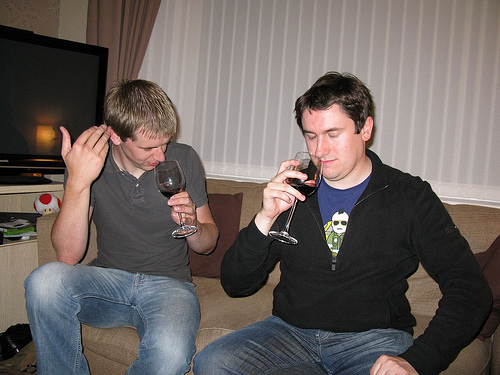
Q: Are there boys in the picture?
A: No, there are no boys.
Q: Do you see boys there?
A: No, there are no boys.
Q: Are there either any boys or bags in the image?
A: No, there are no boys or bags.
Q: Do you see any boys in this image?
A: No, there are no boys.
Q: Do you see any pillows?
A: Yes, there is a pillow.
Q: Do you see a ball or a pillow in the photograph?
A: Yes, there is a pillow.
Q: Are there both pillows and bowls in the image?
A: No, there is a pillow but no bowls.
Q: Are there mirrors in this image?
A: No, there are no mirrors.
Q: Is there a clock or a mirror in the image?
A: No, there are no mirrors or clocks.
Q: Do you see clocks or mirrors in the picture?
A: No, there are no mirrors or clocks.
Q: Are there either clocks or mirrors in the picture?
A: No, there are no mirrors or clocks.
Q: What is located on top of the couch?
A: The pillow is on top of the couch.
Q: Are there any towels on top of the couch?
A: No, there is a pillow on top of the couch.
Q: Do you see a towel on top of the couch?
A: No, there is a pillow on top of the couch.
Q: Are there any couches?
A: Yes, there is a couch.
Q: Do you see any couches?
A: Yes, there is a couch.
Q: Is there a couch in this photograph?
A: Yes, there is a couch.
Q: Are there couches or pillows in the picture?
A: Yes, there is a couch.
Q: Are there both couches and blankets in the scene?
A: No, there is a couch but no blankets.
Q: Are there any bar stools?
A: No, there are no bar stools.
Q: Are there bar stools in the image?
A: No, there are no bar stools.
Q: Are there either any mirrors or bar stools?
A: No, there are no bar stools or mirrors.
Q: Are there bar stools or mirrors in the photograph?
A: No, there are no bar stools or mirrors.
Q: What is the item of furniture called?
A: The piece of furniture is a couch.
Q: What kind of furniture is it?
A: The piece of furniture is a couch.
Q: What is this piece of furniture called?
A: This is a couch.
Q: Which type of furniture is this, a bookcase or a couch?
A: This is a couch.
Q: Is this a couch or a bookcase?
A: This is a couch.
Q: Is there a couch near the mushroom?
A: Yes, there is a couch near the mushroom.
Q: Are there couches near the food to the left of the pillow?
A: Yes, there is a couch near the mushroom.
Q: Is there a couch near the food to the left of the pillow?
A: Yes, there is a couch near the mushroom.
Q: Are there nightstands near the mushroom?
A: No, there is a couch near the mushroom.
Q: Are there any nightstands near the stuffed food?
A: No, there is a couch near the mushroom.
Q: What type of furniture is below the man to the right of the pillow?
A: The piece of furniture is a couch.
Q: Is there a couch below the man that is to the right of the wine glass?
A: Yes, there is a couch below the man.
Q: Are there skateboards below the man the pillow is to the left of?
A: No, there is a couch below the man.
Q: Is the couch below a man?
A: Yes, the couch is below a man.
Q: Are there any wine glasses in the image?
A: Yes, there is a wine glass.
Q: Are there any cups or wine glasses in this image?
A: Yes, there is a wine glass.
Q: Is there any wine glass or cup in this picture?
A: Yes, there is a wine glass.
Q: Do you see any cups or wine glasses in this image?
A: Yes, there is a wine glass.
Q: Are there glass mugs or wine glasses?
A: Yes, there is a glass wine glass.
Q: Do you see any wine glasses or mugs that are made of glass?
A: Yes, the wine glass is made of glass.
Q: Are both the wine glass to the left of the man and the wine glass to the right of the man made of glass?
A: Yes, both the wine glass and the wine glass are made of glass.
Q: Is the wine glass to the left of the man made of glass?
A: Yes, the wineglass is made of glass.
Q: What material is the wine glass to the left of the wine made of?
A: The wine glass is made of glass.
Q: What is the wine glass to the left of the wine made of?
A: The wine glass is made of glass.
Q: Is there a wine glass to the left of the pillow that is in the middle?
A: Yes, there is a wine glass to the left of the pillow.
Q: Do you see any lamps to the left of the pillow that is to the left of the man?
A: No, there is a wine glass to the left of the pillow.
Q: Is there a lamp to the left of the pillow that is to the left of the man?
A: No, there is a wine glass to the left of the pillow.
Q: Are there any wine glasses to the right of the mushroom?
A: Yes, there is a wine glass to the right of the mushroom.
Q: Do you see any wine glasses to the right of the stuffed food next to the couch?
A: Yes, there is a wine glass to the right of the mushroom.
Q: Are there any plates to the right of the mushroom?
A: No, there is a wine glass to the right of the mushroom.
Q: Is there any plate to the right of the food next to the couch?
A: No, there is a wine glass to the right of the mushroom.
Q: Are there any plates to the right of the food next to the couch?
A: No, there is a wine glass to the right of the mushroom.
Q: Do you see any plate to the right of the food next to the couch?
A: No, there is a wine glass to the right of the mushroom.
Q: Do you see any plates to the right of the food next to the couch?
A: No, there is a wine glass to the right of the mushroom.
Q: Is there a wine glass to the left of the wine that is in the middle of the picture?
A: Yes, there is a wine glass to the left of the wine.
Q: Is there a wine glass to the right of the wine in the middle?
A: No, the wine glass is to the left of the wine.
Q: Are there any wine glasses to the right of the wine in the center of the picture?
A: No, the wine glass is to the left of the wine.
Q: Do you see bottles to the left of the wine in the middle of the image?
A: No, there is a wine glass to the left of the wine.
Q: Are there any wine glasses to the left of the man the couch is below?
A: Yes, there is a wine glass to the left of the man.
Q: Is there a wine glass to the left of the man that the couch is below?
A: Yes, there is a wine glass to the left of the man.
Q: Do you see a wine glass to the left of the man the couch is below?
A: Yes, there is a wine glass to the left of the man.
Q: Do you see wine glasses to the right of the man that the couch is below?
A: No, the wine glass is to the left of the man.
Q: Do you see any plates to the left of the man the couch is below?
A: No, there is a wine glass to the left of the man.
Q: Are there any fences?
A: No, there are no fences.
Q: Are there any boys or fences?
A: No, there are no fences or boys.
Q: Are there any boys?
A: No, there are no boys.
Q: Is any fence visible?
A: No, there are no fences.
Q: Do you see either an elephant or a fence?
A: No, there are no fences or elephants.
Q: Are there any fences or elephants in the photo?
A: No, there are no fences or elephants.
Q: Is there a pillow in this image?
A: Yes, there is a pillow.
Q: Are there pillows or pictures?
A: Yes, there is a pillow.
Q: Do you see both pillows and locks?
A: No, there is a pillow but no locks.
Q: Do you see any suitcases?
A: No, there are no suitcases.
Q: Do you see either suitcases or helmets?
A: No, there are no suitcases or helmets.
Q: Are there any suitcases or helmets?
A: No, there are no suitcases or helmets.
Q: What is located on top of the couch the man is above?
A: The pillow is on top of the couch.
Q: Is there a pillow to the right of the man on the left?
A: Yes, there is a pillow to the right of the man.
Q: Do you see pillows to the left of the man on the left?
A: No, the pillow is to the right of the man.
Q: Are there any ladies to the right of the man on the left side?
A: No, there is a pillow to the right of the man.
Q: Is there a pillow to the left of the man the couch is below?
A: Yes, there is a pillow to the left of the man.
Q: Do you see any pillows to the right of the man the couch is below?
A: No, the pillow is to the left of the man.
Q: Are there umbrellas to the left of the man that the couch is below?
A: No, there is a pillow to the left of the man.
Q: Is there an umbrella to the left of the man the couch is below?
A: No, there is a pillow to the left of the man.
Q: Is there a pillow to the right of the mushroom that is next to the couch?
A: Yes, there is a pillow to the right of the mushroom.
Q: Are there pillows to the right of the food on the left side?
A: Yes, there is a pillow to the right of the mushroom.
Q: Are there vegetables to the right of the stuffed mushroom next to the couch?
A: No, there is a pillow to the right of the mushroom.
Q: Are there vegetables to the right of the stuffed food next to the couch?
A: No, there is a pillow to the right of the mushroom.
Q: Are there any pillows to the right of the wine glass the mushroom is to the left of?
A: Yes, there is a pillow to the right of the wineglass.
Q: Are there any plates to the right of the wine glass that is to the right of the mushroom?
A: No, there is a pillow to the right of the wineglass.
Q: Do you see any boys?
A: No, there are no boys.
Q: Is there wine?
A: Yes, there is wine.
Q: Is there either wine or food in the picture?
A: Yes, there is wine.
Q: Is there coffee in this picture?
A: No, there is no coffee.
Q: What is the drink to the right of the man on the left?
A: The drink is wine.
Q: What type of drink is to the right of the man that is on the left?
A: The drink is wine.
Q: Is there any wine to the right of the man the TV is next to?
A: Yes, there is wine to the right of the man.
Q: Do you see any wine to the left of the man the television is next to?
A: No, the wine is to the right of the man.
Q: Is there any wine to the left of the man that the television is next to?
A: No, the wine is to the right of the man.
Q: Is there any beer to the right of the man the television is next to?
A: No, there is wine to the right of the man.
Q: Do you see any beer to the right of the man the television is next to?
A: No, there is wine to the right of the man.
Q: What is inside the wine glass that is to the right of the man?
A: The wine is inside the wineglass.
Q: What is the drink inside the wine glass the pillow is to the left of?
A: The drink is wine.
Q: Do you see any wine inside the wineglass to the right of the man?
A: Yes, there is wine inside the wine glass.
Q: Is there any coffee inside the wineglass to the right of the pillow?
A: No, there is wine inside the wine glass.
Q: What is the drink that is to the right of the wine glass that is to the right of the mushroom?
A: The drink is wine.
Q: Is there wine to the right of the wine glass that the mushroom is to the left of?
A: Yes, there is wine to the right of the wineglass.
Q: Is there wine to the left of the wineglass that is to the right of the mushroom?
A: No, the wine is to the right of the wine glass.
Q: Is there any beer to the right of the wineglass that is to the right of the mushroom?
A: No, there is wine to the right of the wine glass.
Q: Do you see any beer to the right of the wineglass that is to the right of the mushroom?
A: No, there is wine to the right of the wine glass.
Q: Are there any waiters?
A: No, there are no waiters.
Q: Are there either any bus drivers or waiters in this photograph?
A: No, there are no waiters or bus drivers.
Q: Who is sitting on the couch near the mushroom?
A: The man is sitting on the couch.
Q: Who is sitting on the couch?
A: The man is sitting on the couch.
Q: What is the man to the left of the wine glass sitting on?
A: The man is sitting on the couch.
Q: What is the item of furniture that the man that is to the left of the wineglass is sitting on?
A: The piece of furniture is a couch.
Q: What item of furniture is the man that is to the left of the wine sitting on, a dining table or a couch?
A: The man is sitting on a couch.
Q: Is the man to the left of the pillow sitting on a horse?
A: No, the man is sitting on the couch.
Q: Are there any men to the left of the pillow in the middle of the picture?
A: Yes, there is a man to the left of the pillow.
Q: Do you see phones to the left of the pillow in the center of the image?
A: No, there is a man to the left of the pillow.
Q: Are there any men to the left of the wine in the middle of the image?
A: Yes, there is a man to the left of the wine.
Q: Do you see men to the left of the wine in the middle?
A: Yes, there is a man to the left of the wine.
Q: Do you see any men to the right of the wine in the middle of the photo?
A: No, the man is to the left of the wine.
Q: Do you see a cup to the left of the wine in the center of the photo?
A: No, there is a man to the left of the wine.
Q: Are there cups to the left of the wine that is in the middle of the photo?
A: No, there is a man to the left of the wine.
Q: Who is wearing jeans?
A: The man is wearing jeans.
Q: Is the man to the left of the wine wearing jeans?
A: Yes, the man is wearing jeans.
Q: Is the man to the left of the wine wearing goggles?
A: No, the man is wearing jeans.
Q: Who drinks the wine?
A: The man drinks the wine.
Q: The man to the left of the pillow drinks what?
A: The man drinks wine.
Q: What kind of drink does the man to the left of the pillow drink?
A: The man drinks wine.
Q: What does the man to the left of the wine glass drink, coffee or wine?
A: The man drinks wine.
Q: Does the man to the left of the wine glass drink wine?
A: Yes, the man drinks wine.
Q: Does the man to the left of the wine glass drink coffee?
A: No, the man drinks wine.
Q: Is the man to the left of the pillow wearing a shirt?
A: Yes, the man is wearing a shirt.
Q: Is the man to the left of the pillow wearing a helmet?
A: No, the man is wearing a shirt.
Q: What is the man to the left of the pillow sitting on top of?
A: The man is sitting on top of the couch.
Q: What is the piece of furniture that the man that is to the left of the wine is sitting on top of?
A: The piece of furniture is a couch.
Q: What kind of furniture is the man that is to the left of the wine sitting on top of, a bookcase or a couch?
A: The man is sitting on top of a couch.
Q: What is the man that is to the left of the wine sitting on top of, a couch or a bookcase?
A: The man is sitting on top of a couch.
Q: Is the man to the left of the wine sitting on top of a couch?
A: Yes, the man is sitting on top of a couch.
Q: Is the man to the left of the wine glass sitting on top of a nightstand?
A: No, the man is sitting on top of a couch.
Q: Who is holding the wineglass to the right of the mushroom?
A: The man is holding the wineglass.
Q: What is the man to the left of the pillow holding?
A: The man is holding the wine glass.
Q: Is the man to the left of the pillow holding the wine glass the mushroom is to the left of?
A: Yes, the man is holding the wineglass.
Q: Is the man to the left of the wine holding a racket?
A: No, the man is holding the wineglass.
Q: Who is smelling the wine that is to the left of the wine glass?
A: The man is smelling the wine.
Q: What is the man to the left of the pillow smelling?
A: The man is smelling the wine.